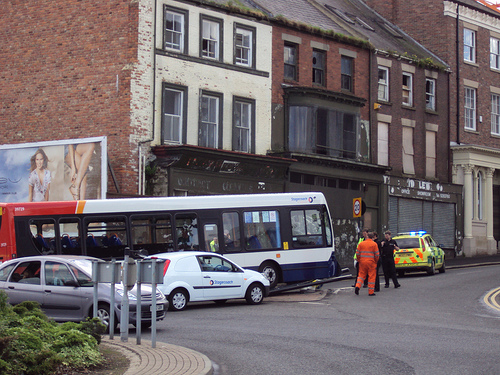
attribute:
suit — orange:
[352, 236, 380, 295]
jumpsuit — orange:
[351, 235, 380, 295]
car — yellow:
[390, 229, 447, 277]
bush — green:
[1, 330, 64, 373]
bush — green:
[20, 311, 59, 334]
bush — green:
[53, 340, 105, 370]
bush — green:
[74, 313, 107, 346]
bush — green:
[10, 296, 38, 318]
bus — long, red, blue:
[13, 191, 369, 291]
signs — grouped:
[61, 256, 169, 340]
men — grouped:
[350, 223, 429, 303]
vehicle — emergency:
[372, 220, 489, 297]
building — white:
[47, 16, 471, 267]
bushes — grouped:
[7, 295, 110, 362]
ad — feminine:
[10, 123, 116, 207]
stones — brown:
[110, 333, 189, 373]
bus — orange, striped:
[7, 186, 419, 286]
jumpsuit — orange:
[355, 240, 390, 294]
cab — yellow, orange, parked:
[371, 220, 428, 259]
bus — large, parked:
[10, 189, 338, 309]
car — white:
[124, 240, 268, 308]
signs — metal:
[94, 249, 204, 343]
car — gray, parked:
[26, 245, 187, 357]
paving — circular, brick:
[166, 302, 423, 359]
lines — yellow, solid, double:
[451, 272, 493, 310]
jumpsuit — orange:
[344, 240, 388, 284]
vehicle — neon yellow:
[388, 232, 478, 277]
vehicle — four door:
[13, 250, 151, 348]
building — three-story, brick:
[3, 1, 463, 264]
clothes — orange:
[353, 238, 379, 293]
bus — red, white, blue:
[1, 191, 337, 285]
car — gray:
[0, 255, 169, 330]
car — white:
[144, 251, 270, 310]